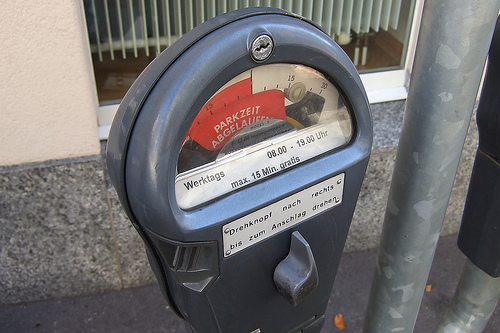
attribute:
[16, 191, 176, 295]
wall — grey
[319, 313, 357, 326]
leaf — brown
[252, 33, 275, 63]
lock — silver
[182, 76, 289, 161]
label — red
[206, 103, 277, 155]
letters — white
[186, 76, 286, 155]
label — red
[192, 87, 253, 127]
numbers — black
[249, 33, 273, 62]
keyhole — silver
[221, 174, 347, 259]
label — white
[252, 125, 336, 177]
numbers — black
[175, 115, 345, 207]
label — white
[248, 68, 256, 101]
line — black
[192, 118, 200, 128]
line — black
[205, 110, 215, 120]
line — black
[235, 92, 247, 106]
line — black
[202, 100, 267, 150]
lettering — white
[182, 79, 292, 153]
background — red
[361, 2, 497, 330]
pole — silver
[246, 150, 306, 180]
numbers — black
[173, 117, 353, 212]
background — white